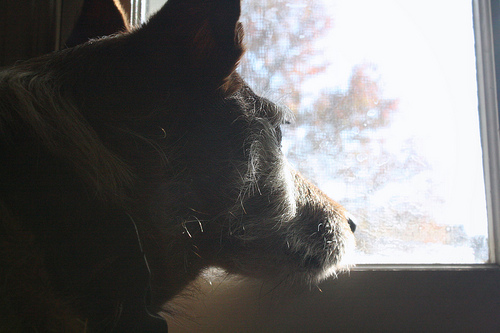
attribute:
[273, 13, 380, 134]
tree — big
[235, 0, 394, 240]
tree — blurry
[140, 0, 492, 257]
window — glass, rectangular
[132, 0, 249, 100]
ear — furry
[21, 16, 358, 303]
dog fur — white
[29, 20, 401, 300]
dog — grey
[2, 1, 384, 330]
dog — hairy, old, brown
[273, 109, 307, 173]
eyes — open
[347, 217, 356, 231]
nose — black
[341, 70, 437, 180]
window — bright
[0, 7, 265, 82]
ears — pointy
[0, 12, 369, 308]
dog — old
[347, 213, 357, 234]
nose — black, small